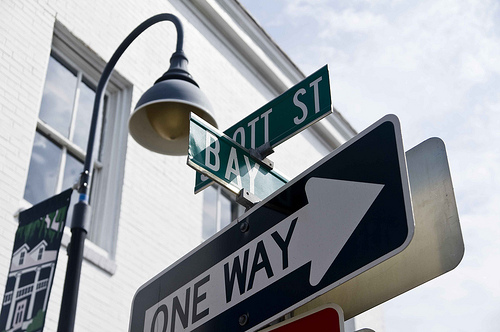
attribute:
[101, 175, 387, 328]
arrow — white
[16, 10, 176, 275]
window — glass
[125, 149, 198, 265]
wall — white, brick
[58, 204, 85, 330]
pole — black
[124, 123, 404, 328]
sign — black, white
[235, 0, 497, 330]
sky — blue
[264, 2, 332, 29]
cloud — puffy, white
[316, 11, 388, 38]
cloud — puffy, white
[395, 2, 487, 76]
cloud — puffy, white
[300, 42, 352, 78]
cloud — puffy, white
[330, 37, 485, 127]
cloud — puffy, white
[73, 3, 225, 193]
lamp — metal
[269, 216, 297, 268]
letter — black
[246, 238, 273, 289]
letter — black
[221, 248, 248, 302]
letter — black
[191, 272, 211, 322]
letter — black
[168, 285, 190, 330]
letter — black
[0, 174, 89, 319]
banner — decorative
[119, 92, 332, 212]
sign — printed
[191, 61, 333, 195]
sign — white, green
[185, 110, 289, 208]
sign — white, green